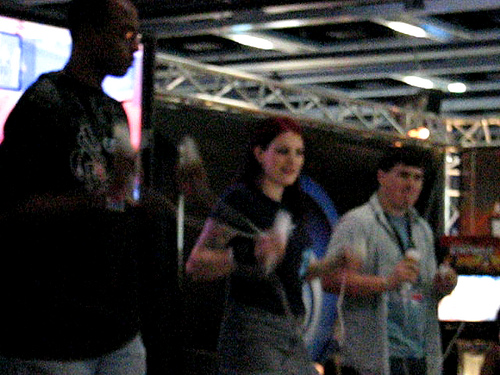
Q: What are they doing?
A: Playing WII.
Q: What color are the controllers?
A: White.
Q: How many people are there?
A: 3.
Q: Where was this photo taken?
A: Gaming station.